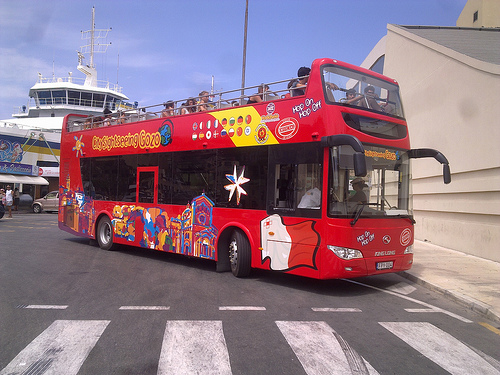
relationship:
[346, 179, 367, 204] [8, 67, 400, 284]
driver in bus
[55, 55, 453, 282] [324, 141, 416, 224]
bus has window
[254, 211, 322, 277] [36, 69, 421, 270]
flag on bus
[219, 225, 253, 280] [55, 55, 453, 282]
wheel on bus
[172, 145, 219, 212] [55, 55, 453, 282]
window on bus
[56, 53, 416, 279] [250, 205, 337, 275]
bus has painted flag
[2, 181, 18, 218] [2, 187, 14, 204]
person wearing shirt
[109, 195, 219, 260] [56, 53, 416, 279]
drawings on side of bus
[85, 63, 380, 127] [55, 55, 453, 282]
people on top of bus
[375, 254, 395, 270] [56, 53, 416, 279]
license plate on bus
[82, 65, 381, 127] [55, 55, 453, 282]
people on bus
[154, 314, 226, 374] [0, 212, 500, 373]
line on grey road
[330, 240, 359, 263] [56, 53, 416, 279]
light on bus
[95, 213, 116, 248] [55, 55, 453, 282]
rear wheel on bus